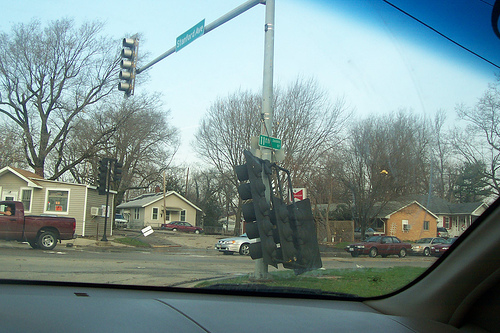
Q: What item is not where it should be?
A: Traffic light.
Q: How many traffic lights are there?
A: Two.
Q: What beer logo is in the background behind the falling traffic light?
A: Budweiser.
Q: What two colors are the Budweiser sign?
A: Red, white.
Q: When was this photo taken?
A: Daytime.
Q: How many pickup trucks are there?
A: One.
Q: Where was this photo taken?
A: On a city street.